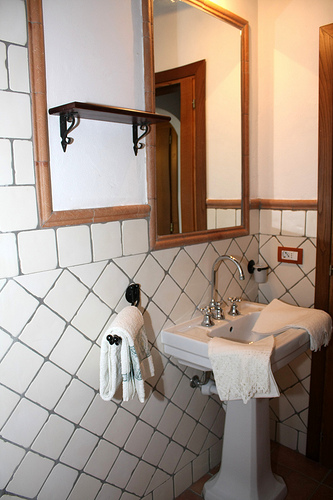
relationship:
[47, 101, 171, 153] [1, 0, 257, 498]
shelf mounted on wall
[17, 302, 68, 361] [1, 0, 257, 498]
tile on wall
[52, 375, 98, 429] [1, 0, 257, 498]
tile on wall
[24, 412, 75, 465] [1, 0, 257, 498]
tile on wall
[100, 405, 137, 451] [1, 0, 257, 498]
tile on wall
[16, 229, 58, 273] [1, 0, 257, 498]
tile on wall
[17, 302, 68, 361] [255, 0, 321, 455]
tile on wall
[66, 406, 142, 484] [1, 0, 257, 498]
tiles mounted on wall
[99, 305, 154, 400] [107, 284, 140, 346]
towel mounted on rack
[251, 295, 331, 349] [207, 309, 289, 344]
towel mounted on basin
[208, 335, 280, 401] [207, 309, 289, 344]
towel mounted on basin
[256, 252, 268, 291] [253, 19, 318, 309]
cup holder holder on wall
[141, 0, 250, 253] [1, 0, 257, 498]
mirror mounted on wall